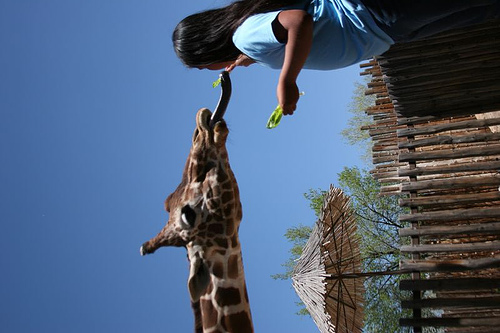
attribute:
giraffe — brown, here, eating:
[139, 109, 276, 331]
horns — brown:
[135, 228, 172, 264]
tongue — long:
[206, 70, 238, 127]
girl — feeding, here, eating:
[171, 4, 499, 117]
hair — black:
[172, 0, 274, 71]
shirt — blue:
[232, 0, 404, 77]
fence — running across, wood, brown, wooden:
[392, 41, 499, 329]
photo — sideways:
[1, 2, 495, 332]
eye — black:
[178, 200, 198, 233]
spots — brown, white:
[201, 286, 241, 327]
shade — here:
[387, 31, 500, 127]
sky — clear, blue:
[7, 3, 162, 228]